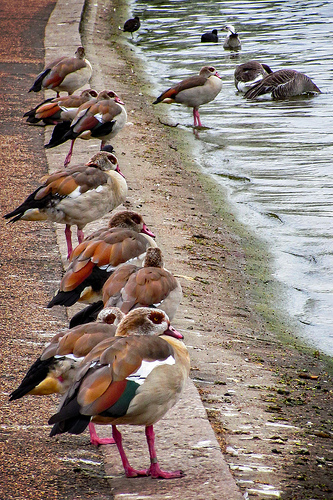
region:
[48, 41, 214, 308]
the birds are by the water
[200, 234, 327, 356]
mold is by the water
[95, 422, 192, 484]
the bird has pink legs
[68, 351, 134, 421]
the bird has multicolored feathers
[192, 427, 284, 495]
snow is on the ground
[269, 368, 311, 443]
dirt and debris is on the ground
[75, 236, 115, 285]
the bird has orange feathers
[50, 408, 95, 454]
the bird has a black tail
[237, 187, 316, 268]
the water has waves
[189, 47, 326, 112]
birds are in the water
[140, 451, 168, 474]
silver tag on birds leg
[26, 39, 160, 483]
row of ducks standing near edge of water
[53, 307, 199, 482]
duck with various colored feathers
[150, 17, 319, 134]
ducks in the water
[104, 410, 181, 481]
duck with red legs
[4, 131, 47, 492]
walk way covered with tiny leaves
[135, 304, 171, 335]
brown feathers around ducks eye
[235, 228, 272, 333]
green algae at waters edge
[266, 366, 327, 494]
leave and debris along waters edge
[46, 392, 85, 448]
black tail feathers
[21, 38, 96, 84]
brown and white bird on sidewalk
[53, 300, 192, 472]
brown and white bird on sidewalk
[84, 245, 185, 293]
brown and white bird on sidewalk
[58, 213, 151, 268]
brown and white bird on sidewalk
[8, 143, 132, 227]
brown and white bird on sidewalk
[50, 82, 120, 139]
brown and white bird on sidewalk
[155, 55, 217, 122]
brown and white bird on sidewalk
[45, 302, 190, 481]
brown and white bird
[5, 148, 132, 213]
brown and white bird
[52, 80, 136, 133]
brown and white bird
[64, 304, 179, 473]
bird near a lake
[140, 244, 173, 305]
bird near a lake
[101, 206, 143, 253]
bird near a lake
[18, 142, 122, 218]
bird near a lake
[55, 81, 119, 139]
bird near a lake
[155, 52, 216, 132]
bird near a lake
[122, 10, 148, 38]
bird near a lake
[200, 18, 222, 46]
bird in a lake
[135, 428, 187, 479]
leg of a bird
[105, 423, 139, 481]
leg on a bird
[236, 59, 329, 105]
The bird is in the water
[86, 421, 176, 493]
the bird has pink feet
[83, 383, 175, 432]
the birds wing has yellow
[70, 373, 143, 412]
the birds wing is red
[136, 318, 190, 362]
the birds beek is pink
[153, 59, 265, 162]
the bird is standing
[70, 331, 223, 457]
the bird is multicolored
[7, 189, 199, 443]
the birds are standing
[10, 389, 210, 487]
the bidrds have pink feet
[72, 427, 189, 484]
the feet of the bird is pink